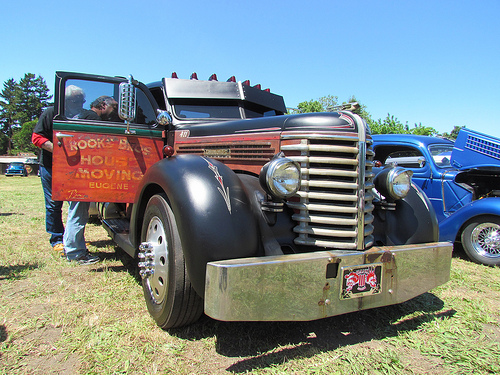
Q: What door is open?
A: The door on a truck,.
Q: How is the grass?
A: Worn down.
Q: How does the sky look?
A: Blue and clear.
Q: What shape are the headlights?
A: Round.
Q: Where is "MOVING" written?
A: On car door.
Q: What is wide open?
A: A car door.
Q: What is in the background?
A: Green trees.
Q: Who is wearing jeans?
A: Two men.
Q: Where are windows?
A: On the cars.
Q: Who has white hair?
A: Man on the left.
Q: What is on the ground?
A: Weeds.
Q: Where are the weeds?
A: On the ground.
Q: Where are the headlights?
A: On the front of the vehicle.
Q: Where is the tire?
A: On the side of the truck.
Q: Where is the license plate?
A: On the front of the truck.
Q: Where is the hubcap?
A: On the tire.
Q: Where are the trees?
A: Behind the vehicles.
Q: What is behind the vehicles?
A: The trees.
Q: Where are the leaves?
A: On the trees.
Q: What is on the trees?
A: Leaves.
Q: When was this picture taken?
A: Daytime.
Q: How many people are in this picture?
A: 2.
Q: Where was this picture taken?
A: Car show.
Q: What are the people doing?
A: Looking inside car.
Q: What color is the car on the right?
A: Blue.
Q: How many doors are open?
A: 1.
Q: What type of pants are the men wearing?
A: Jeans.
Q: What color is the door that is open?
A: Brown.